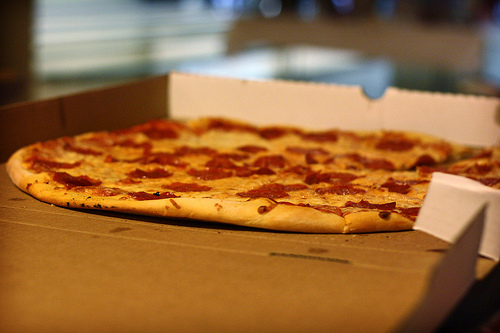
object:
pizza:
[3, 114, 500, 232]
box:
[1, 70, 498, 331]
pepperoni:
[234, 187, 294, 200]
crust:
[3, 141, 421, 235]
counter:
[438, 261, 499, 333]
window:
[25, 0, 149, 39]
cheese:
[52, 125, 473, 205]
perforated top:
[167, 74, 499, 106]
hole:
[359, 86, 390, 105]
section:
[0, 207, 495, 285]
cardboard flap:
[411, 171, 499, 262]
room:
[1, 0, 500, 333]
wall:
[1, 0, 35, 103]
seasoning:
[52, 189, 123, 212]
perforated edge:
[4, 65, 497, 117]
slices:
[6, 115, 499, 231]